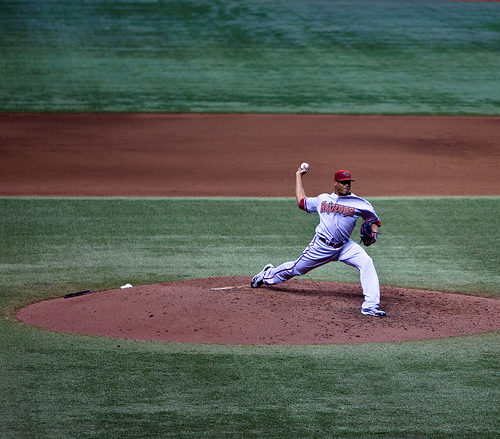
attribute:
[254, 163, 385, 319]
baseball player — wide stanced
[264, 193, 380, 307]
uniform — grey, gray, white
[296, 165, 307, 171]
hand — on the right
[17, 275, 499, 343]
mound — brown, dirt, for pitcher, red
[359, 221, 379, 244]
hand — gloved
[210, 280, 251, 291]
line — white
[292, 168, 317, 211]
arm — right arm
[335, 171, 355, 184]
cap — red, baseball team cap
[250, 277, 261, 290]
toe — pointed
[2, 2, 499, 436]
grass — green, lush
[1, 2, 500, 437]
field — green, brown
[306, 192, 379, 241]
shirt — short sleeved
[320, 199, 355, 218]
letters — red, arizona, logo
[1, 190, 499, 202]
line — white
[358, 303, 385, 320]
foot — left foot, right foot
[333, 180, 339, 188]
ear — brown